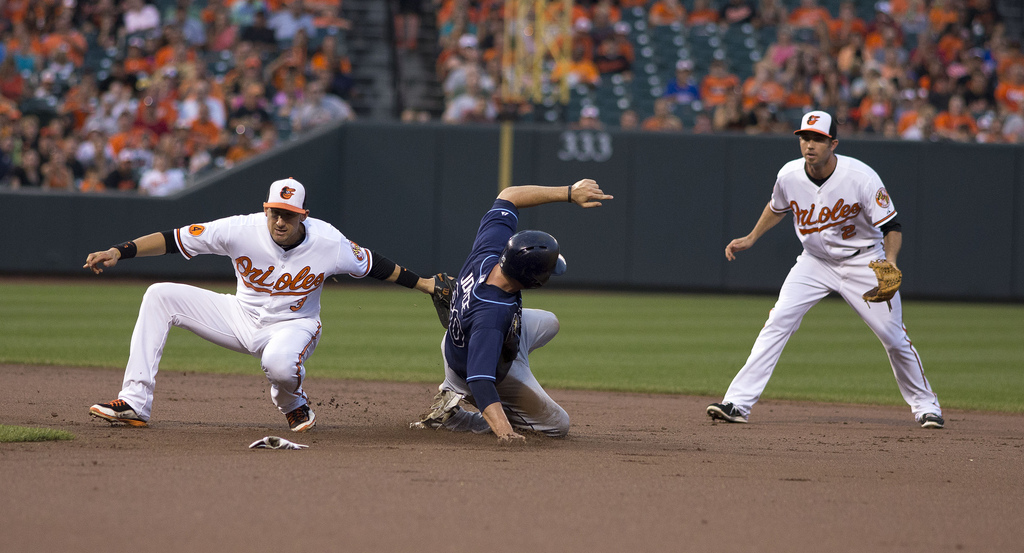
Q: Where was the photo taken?
A: At the baseball park.